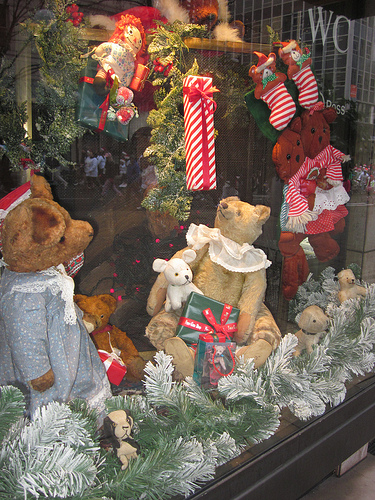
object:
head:
[277, 38, 304, 67]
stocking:
[290, 65, 319, 110]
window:
[1, 0, 375, 498]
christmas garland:
[181, 75, 217, 190]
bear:
[248, 50, 296, 132]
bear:
[271, 39, 318, 109]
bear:
[71, 292, 155, 380]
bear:
[299, 106, 350, 234]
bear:
[338, 268, 367, 306]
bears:
[145, 195, 282, 380]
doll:
[94, 13, 146, 95]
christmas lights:
[109, 286, 115, 294]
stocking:
[260, 81, 296, 130]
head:
[248, 50, 278, 84]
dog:
[151, 247, 204, 312]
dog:
[292, 304, 330, 359]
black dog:
[103, 408, 141, 470]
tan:
[102, 415, 120, 453]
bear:
[0, 196, 112, 434]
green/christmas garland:
[174, 290, 240, 343]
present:
[78, 66, 129, 143]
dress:
[0, 262, 114, 435]